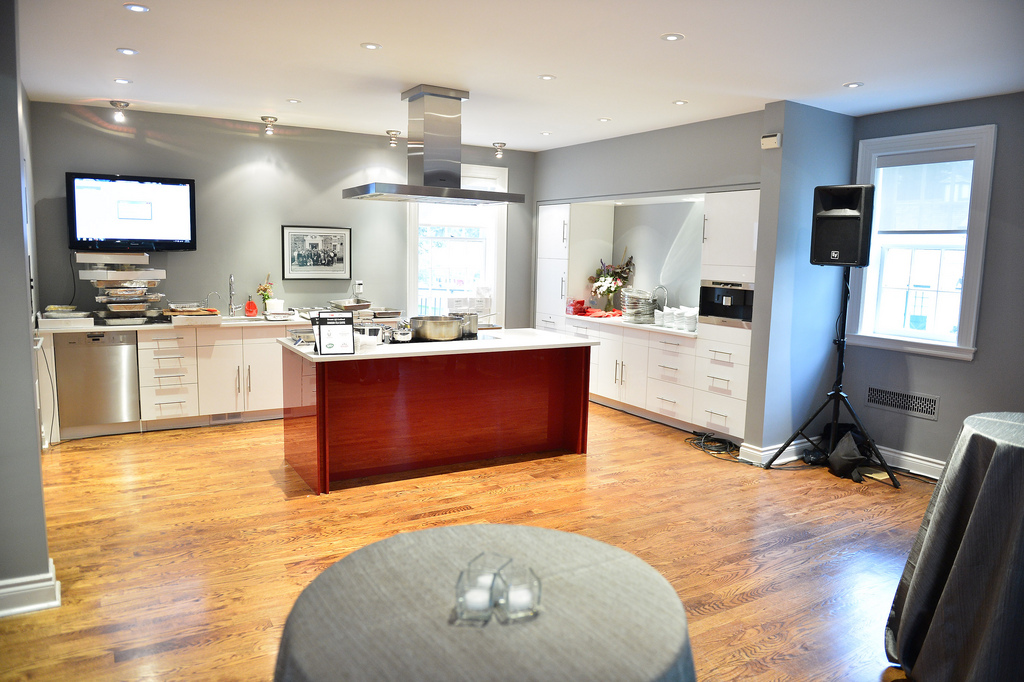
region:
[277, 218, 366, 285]
Picture on the wall.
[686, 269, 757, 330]
A built in microwave.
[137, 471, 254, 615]
Hardwood floors in the kitchen.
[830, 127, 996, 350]
Window in the kitchen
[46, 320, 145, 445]
Silver dishwasher in the kitchen.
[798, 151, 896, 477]
Tall speaker in the corner.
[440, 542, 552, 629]
Candles in the middle of the table.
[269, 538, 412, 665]
Grey table cloth under the candles.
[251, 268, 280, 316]
Vase of flowers on the counter.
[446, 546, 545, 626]
the candles are the centerpiece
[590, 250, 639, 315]
the flowers on the counter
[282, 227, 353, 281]
the picture on the wall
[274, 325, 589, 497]
the brown island counter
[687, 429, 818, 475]
the black cord on the ground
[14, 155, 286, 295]
The black tv is on the grey wall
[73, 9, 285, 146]
The lights are in the ceiling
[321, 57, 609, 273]
The oven hood is stainless steel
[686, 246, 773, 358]
The oven is black and stainless steel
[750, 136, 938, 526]
The black speaker is on a black stand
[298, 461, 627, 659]
The candles are on the table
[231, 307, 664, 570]
The island has a brown wooden base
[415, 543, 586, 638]
The candle is in a glass bowl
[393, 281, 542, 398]
The silver pot is on the stove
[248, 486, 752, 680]
gray table with three glasses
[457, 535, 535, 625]
white candles on glass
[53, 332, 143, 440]
silver automatic dishwasher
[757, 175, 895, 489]
speaker on a tripod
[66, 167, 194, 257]
large flat screen TV in kitchen area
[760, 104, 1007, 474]
grey wall with thite trim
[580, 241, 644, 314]
flowers on a counter top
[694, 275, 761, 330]
built in microwave oven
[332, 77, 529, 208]
over stove exhaust fan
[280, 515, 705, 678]
grey table cloth on round table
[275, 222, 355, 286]
picture in a black frame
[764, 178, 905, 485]
a black tripod mounted speaker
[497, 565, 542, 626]
a square glass candle holder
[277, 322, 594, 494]
a wood and marble kitchen island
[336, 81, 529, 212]
a modern, silver kitchen vent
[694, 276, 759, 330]
an inset silver microwave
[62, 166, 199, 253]
a black flat screen tv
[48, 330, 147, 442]
a silver built in dish washer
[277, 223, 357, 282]
a black and white printed painting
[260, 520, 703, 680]
a round, grey table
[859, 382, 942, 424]
a grey detailed wall vent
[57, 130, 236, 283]
flat screen tv on wall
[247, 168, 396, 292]
framed picture on wall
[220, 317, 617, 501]
counter in middle of kitchen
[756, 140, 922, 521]
speaker on stand in room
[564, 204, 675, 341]
vase of flowers on counter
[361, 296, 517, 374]
pots on stove top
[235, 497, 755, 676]
round table in room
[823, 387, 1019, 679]
grey table cloth on table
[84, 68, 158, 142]
light fixture in ceiling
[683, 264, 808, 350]
stainless steel oven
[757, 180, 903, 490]
a black speaker on a black stand